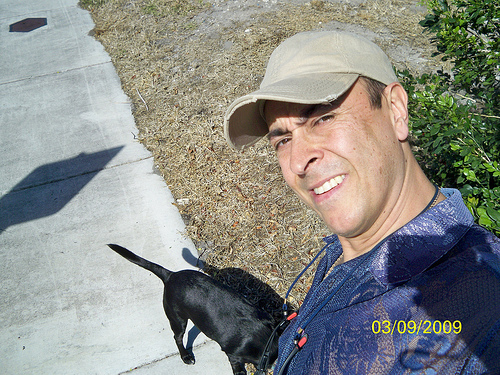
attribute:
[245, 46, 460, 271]
man — dark, standing, looking, walking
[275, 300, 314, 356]
sunglasses — hanging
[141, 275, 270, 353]
dog — black, small, walking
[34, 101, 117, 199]
street — paved, white, cracked, grey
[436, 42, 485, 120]
leaves — green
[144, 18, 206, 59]
grass — brown